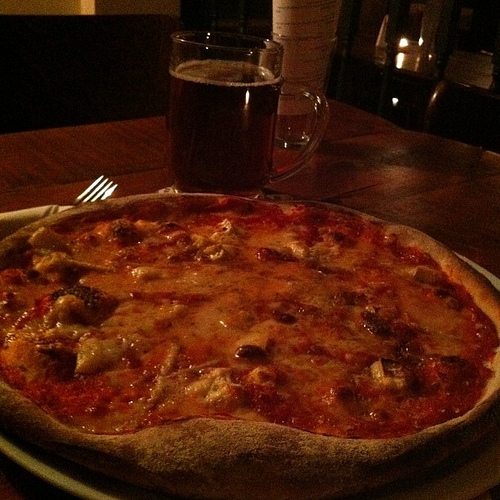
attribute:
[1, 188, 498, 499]
dish — ceramic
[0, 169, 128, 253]
fork — silver, wrapped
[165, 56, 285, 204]
beer — brown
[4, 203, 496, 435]
sauce — tomato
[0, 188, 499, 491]
crust — brown, thick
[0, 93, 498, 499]
table — square, wooden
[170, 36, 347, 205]
mug — glass, beer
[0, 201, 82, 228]
wrap — napkin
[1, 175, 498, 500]
pizza — round, cheesy, white